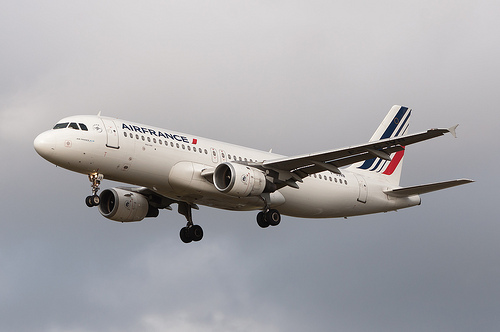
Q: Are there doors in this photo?
A: Yes, there is a door.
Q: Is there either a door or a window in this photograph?
A: Yes, there is a door.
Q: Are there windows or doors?
A: Yes, there is a door.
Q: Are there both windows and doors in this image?
A: Yes, there are both a door and windows.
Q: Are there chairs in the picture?
A: No, there are no chairs.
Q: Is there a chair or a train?
A: No, there are no chairs or trains.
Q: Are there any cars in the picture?
A: No, there are no cars.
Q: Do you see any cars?
A: No, there are no cars.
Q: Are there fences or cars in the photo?
A: No, there are no cars or fences.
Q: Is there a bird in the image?
A: No, there are no birds.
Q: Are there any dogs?
A: No, there are no dogs.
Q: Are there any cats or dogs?
A: No, there are no dogs or cats.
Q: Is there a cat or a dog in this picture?
A: No, there are no dogs or cats.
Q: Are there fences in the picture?
A: No, there are no fences.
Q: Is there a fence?
A: No, there are no fences.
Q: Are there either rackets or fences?
A: No, there are no fences or rackets.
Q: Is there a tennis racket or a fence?
A: No, there are no fences or rackets.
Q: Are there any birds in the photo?
A: No, there are no birds.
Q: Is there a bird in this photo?
A: No, there are no birds.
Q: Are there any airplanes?
A: Yes, there is an airplane.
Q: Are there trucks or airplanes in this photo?
A: Yes, there is an airplane.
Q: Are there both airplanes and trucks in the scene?
A: No, there is an airplane but no trucks.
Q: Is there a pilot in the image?
A: No, there are no pilots.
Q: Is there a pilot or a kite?
A: No, there are no pilots or kites.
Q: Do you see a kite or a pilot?
A: No, there are no pilots or kites.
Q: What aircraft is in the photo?
A: The aircraft is an airplane.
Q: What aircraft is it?
A: The aircraft is an airplane.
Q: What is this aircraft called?
A: This is an airplane.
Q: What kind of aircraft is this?
A: This is an airplane.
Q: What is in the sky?
A: The plane is in the sky.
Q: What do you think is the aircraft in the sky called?
A: The aircraft is an airplane.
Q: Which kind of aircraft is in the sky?
A: The aircraft is an airplane.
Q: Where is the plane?
A: The plane is in the sky.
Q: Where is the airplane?
A: The plane is in the sky.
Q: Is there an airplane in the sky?
A: Yes, there is an airplane in the sky.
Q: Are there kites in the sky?
A: No, there is an airplane in the sky.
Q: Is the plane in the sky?
A: Yes, the plane is in the sky.